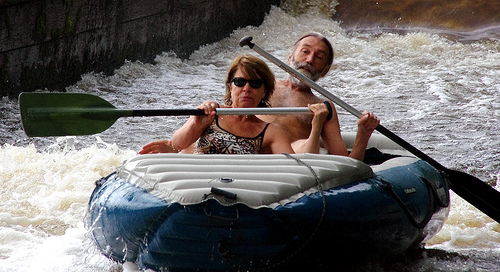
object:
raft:
[85, 132, 451, 272]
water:
[0, 0, 500, 272]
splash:
[0, 137, 77, 242]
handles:
[380, 170, 450, 230]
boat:
[87, 132, 451, 272]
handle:
[202, 187, 237, 200]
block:
[0, 0, 273, 101]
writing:
[274, 64, 317, 88]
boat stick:
[238, 35, 500, 224]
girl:
[171, 53, 329, 154]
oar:
[18, 92, 333, 137]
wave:
[385, 40, 467, 102]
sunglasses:
[229, 77, 263, 89]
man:
[253, 31, 381, 162]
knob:
[239, 34, 256, 49]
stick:
[239, 35, 443, 171]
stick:
[119, 106, 310, 116]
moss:
[39, 19, 59, 58]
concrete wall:
[1, 1, 99, 67]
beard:
[286, 56, 328, 89]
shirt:
[193, 115, 271, 154]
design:
[203, 132, 217, 148]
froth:
[0, 152, 87, 223]